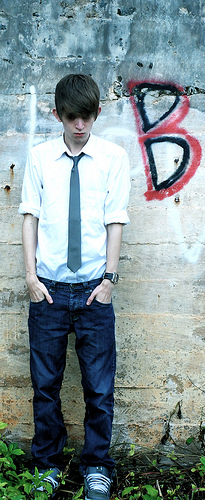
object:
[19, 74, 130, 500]
young man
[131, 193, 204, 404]
wall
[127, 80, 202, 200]
graffiti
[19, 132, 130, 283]
shirt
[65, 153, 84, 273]
tie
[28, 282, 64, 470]
jeans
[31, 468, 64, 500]
skater shoe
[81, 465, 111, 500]
skater shoe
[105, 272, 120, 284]
watch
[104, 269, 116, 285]
wrist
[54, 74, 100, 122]
hair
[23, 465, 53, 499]
plants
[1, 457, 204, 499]
ground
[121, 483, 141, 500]
plants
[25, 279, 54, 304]
hand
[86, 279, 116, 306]
hand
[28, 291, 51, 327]
pocket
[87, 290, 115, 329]
pocket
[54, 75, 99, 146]
head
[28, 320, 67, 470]
leg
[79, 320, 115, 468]
leg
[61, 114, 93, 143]
face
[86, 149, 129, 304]
arm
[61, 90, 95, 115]
bangs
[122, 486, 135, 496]
leaf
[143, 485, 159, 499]
leaf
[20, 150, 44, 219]
sleeve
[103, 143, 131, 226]
sleeve